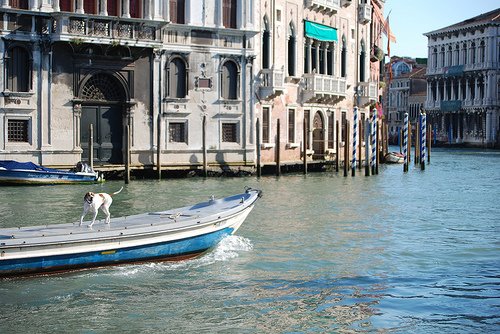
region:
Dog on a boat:
[74, 185, 126, 239]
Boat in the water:
[3, 178, 267, 274]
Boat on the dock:
[1, 155, 104, 185]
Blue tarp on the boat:
[1, 158, 68, 175]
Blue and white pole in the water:
[368, 108, 377, 176]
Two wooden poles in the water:
[256, 120, 283, 180]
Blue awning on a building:
[303, 18, 341, 44]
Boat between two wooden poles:
[383, 150, 412, 170]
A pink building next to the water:
[258, 0, 369, 182]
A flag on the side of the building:
[371, 10, 396, 57]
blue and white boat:
[0, 186, 261, 277]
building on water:
[2, 0, 392, 170]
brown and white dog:
[81, 191, 115, 222]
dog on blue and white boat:
[78, 192, 116, 219]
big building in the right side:
[425, 16, 497, 147]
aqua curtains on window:
[305, 22, 343, 39]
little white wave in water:
[114, 232, 251, 273]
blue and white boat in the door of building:
[0, 159, 105, 183]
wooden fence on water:
[268, 102, 429, 190]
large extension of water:
[1, 136, 498, 330]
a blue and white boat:
[16, 169, 256, 273]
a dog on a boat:
[73, 178, 128, 233]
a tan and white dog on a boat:
[77, 181, 128, 231]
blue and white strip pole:
[347, 105, 360, 172]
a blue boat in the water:
[2, 158, 105, 190]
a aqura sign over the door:
[307, 21, 339, 44]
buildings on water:
[0, 3, 405, 183]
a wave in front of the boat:
[159, 231, 272, 277]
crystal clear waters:
[335, 171, 497, 310]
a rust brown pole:
[341, 119, 353, 179]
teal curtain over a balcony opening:
[303, 15, 339, 45]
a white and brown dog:
[79, 183, 128, 224]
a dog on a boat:
[79, 185, 122, 228]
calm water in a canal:
[358, 186, 454, 283]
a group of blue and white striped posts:
[347, 96, 433, 174]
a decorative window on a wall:
[159, 45, 194, 105]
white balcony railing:
[304, 66, 347, 103]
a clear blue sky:
[402, 8, 419, 46]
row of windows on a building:
[428, 76, 490, 109]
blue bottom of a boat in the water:
[12, 246, 234, 281]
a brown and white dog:
[80, 185, 125, 226]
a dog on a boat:
[0, 184, 268, 282]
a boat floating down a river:
[0, 188, 267, 275]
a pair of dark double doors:
[80, 105, 127, 165]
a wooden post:
[200, 115, 212, 180]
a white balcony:
[301, 73, 346, 103]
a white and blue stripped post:
[418, 111, 428, 163]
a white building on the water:
[423, 6, 498, 146]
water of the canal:
[1, 146, 497, 332]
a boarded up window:
[168, 58, 190, 98]